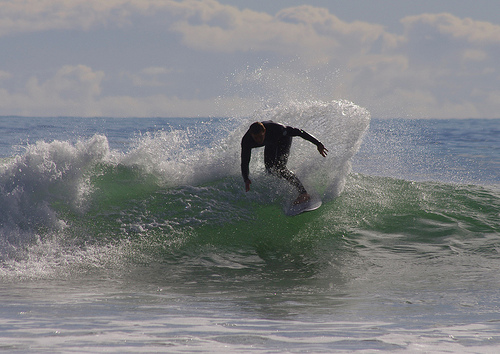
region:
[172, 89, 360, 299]
a man on a surfboard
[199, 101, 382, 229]
a man riding a surfboard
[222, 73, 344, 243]
a man on the water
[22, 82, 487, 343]
a body of water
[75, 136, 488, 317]
a body of blue water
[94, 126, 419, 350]
a body of water with waves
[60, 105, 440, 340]
a body of water with large waves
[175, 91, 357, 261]
a man wearing a wetsuit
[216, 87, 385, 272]
a man wearing a black wetsuit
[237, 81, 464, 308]
a man surfing a wave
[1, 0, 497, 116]
white puffy clouds in sky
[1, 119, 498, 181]
surface of ocean water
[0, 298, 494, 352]
sea foam on water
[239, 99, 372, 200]
water spray from surfboard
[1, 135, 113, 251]
white water from crashed wave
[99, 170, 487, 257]
wall of green wave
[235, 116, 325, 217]
surfboarder leaning forward over water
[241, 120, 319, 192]
wetsuit on body of surfer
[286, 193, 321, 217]
foot on white board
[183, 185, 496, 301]
light reflection on wave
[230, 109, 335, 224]
a surfer in the sea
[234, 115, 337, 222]
man wears a wet suit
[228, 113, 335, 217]
man is bend forward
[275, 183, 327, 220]
a white surfboard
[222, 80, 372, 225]
a splash above the surfboard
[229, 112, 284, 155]
man has black hair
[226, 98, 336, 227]
man stands on surfboard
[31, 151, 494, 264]
water of wave is color green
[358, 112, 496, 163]
water is color blue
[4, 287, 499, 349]
foam in the water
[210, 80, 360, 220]
The man is on a surfboard.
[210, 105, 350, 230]
The man is wearing a wetsuit.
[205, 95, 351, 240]
The man's wetsuit is black.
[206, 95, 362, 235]
The surfboard is white.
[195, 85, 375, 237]
The wetsuit is wet.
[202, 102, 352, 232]
The wetsuit has long sleeves.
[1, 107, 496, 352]
The water is splashing.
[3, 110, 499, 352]
The water is wavy.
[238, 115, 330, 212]
surfer in black wetsuit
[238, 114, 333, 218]
surfer catching wave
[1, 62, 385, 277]
white foamy wave water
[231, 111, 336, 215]
surfer leaning forward on surfboard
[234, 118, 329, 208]
surfer appears to be losing balance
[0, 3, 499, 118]
fluffy white clouds in sky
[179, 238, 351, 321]
shadow of surfer in water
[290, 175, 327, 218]
lavender solid-colored surfboard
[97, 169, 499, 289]
greenish water under wave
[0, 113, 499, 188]
blue water behind wave